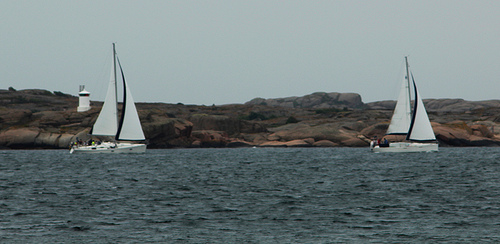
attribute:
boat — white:
[67, 141, 147, 154]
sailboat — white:
[69, 40, 147, 157]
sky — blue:
[2, 0, 499, 105]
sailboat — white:
[364, 52, 453, 160]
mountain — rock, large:
[244, 89, 373, 119]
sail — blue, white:
[405, 60, 437, 142]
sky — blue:
[153, 3, 326, 105]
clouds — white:
[3, 10, 494, 87]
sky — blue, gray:
[3, 3, 493, 95]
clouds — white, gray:
[194, 17, 320, 89]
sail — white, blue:
[402, 74, 436, 142]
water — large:
[157, 189, 374, 233]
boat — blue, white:
[368, 56, 438, 152]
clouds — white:
[1, 0, 499, 103]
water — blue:
[19, 162, 483, 230]